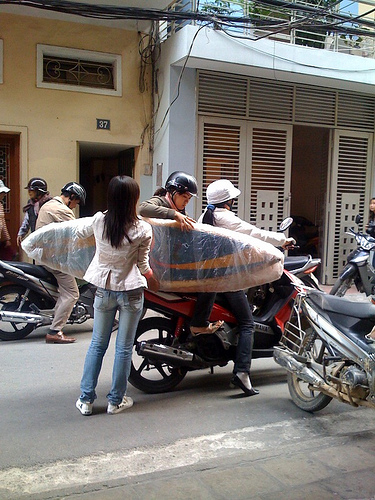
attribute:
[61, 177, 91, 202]
helmet — black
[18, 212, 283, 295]
board — Big 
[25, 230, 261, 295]
board — Big 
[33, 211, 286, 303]
board — Big 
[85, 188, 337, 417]
scooter — red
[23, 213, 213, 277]
board — big